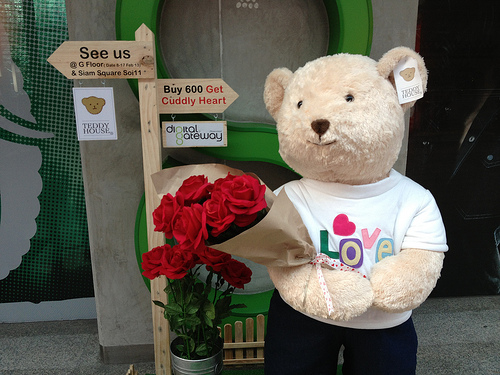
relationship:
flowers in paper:
[134, 161, 315, 293] [149, 163, 323, 265]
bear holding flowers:
[259, 43, 449, 372] [127, 161, 276, 288]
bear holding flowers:
[234, 49, 443, 343] [150, 165, 274, 258]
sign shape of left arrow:
[41, 30, 155, 87] [154, 65, 239, 115]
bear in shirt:
[259, 43, 449, 372] [264, 170, 449, 330]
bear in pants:
[259, 43, 449, 372] [260, 289, 425, 373]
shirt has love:
[271, 163, 451, 333] [315, 224, 399, 269]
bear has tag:
[259, 43, 449, 372] [391, 58, 422, 102]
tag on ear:
[391, 58, 422, 102] [376, 45, 427, 110]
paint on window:
[0, 140, 44, 284] [1, 0, 93, 305]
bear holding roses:
[259, 43, 449, 372] [139, 162, 267, 253]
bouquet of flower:
[132, 167, 359, 296] [217, 174, 264, 217]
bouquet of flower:
[132, 167, 359, 296] [175, 171, 208, 201]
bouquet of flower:
[132, 167, 359, 296] [147, 187, 180, 239]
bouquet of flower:
[132, 167, 359, 296] [141, 240, 171, 282]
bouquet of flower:
[132, 167, 359, 296] [190, 190, 239, 236]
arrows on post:
[42, 36, 243, 121] [126, 79, 174, 368]